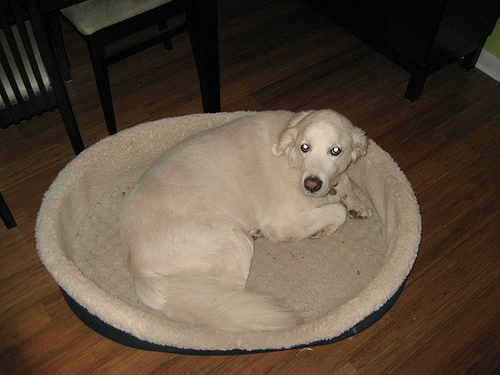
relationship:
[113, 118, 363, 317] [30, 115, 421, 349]
dog on bed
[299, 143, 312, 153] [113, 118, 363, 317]
eye of dog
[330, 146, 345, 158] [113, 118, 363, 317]
eye of dog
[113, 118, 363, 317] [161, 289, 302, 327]
dog has tail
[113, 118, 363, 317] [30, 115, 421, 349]
dog lying on bed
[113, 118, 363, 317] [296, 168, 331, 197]
dog has snout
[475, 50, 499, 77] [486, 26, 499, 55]
trim on wall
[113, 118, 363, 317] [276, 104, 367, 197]
dog has head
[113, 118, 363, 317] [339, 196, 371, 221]
dog has paw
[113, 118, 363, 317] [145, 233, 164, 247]
dog has hair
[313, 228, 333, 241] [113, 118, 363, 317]
paw on dog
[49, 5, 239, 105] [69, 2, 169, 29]
chair has cushion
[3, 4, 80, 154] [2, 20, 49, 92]
chair has cushion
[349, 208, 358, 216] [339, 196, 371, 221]
pad on paw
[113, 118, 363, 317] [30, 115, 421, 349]
dog in bed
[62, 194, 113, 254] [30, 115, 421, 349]
inside of bed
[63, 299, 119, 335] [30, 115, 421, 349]
outside of bed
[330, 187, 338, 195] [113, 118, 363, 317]
tag on dog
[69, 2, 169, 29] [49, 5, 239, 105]
cushion on chair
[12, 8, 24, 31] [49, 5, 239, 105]
spindle on chair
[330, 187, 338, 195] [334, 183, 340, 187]
tag on collar